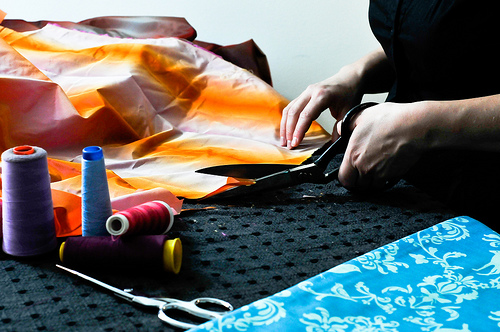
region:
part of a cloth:
[257, 227, 283, 258]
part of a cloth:
[348, 252, 401, 304]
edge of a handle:
[160, 312, 175, 324]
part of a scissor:
[169, 287, 202, 318]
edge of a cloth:
[327, 256, 363, 280]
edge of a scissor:
[226, 155, 253, 173]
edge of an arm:
[411, 87, 455, 121]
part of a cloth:
[158, 149, 200, 200]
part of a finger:
[294, 95, 326, 120]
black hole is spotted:
[233, 258, 243, 269]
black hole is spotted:
[230, 263, 244, 277]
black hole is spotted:
[236, 265, 247, 287]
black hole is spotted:
[234, 263, 241, 285]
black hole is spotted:
[237, 257, 246, 281]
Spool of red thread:
[107, 196, 175, 238]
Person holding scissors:
[191, 96, 448, 207]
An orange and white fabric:
[0, 39, 335, 243]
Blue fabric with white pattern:
[164, 215, 498, 330]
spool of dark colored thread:
[50, 232, 187, 284]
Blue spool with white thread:
[72, 145, 115, 240]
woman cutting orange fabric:
[193, 1, 499, 196]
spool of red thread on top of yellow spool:
[62, 198, 181, 280]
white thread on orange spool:
[0, 135, 62, 260]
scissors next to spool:
[51, 252, 236, 329]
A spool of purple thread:
[7, 138, 58, 277]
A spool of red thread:
[100, 191, 202, 250]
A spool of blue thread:
[74, 138, 119, 251]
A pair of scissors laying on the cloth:
[50, 251, 252, 330]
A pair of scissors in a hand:
[229, 99, 401, 221]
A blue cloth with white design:
[178, 218, 498, 330]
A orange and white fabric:
[25, 23, 324, 197]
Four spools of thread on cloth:
[2, 125, 192, 285]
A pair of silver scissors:
[46, 250, 212, 330]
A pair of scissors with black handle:
[206, 105, 421, 235]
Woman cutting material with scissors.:
[196, 68, 493, 213]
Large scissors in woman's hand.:
[191, 94, 394, 205]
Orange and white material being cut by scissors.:
[88, 53, 304, 197]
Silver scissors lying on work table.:
[52, 254, 241, 330]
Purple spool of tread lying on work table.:
[58, 232, 196, 289]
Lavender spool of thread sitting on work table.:
[2, 143, 63, 269]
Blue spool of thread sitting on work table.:
[70, 141, 111, 234]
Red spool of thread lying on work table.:
[109, 194, 183, 237]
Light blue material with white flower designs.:
[287, 246, 496, 329]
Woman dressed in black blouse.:
[366, 6, 498, 218]